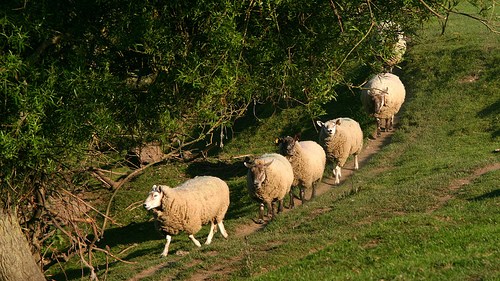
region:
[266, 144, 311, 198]
Sheep waling to pasture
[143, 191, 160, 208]
White head of a sheep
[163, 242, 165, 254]
White leg of a sheep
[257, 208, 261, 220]
A dark sheep leg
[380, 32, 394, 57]
Leaves covering a sheep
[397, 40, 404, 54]
Sheep visible through leaves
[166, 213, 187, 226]
Wool on a sheep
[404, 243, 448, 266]
A surface with green grass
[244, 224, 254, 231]
A path on the grass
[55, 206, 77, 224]
Dry twigs on a tree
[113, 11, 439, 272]
row of white sheep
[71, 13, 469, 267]
row of white sheep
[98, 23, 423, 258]
row of white sheep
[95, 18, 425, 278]
row of white sheep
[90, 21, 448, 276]
row of white sheep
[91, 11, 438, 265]
row of white sheep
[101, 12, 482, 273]
row of white sheep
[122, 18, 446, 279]
row of white sheep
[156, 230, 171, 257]
white color sheep leg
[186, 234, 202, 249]
white color sheep leg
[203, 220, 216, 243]
white color sheep leg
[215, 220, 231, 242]
white color sheep leg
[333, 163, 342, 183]
white color sheep leg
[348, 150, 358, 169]
white color sheep leg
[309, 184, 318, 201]
brown color sheep leg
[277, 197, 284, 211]
brown color sheep leg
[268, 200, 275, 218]
brown color sheep leg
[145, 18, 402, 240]
sheep walking on path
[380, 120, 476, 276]
green and brown ground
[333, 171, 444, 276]
green and short grass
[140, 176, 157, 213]
sheep has white face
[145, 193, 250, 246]
sheep has brown wool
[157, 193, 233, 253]
sheep has white legs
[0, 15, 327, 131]
green leaves on tree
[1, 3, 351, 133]
tree is over sheep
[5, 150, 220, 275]
thin branches on tree